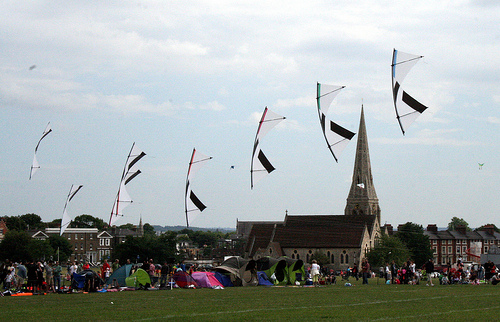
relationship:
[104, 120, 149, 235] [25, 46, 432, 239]
kite in row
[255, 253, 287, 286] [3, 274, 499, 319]
tent on grass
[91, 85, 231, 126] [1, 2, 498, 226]
cloud in sky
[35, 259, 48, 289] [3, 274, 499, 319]
person on grass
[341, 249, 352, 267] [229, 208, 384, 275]
window of church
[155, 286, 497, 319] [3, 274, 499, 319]
line on grass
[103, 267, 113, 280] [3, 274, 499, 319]
person on grass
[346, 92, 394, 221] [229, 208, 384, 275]
steeple on church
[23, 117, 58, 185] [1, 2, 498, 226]
kite in sky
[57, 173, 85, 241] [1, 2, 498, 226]
kite in sky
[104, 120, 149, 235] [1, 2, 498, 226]
kite in sky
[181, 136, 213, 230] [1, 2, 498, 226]
kite in sky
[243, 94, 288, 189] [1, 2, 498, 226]
kite in sky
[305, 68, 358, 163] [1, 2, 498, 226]
kite in sky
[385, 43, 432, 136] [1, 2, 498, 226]
kite in sky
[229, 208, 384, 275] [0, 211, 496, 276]
church in city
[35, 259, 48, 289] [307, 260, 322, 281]
person wearing top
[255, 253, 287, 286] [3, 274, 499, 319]
tent in grass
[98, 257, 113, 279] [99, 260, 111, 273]
person wearing sleeve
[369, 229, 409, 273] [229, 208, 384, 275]
tree near church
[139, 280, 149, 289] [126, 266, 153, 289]
person in tent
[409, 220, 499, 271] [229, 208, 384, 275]
building right of church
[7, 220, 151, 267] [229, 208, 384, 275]
building left of church